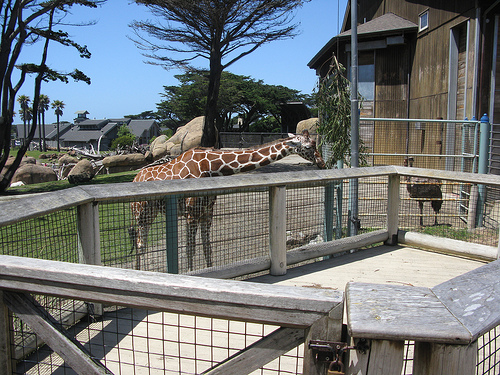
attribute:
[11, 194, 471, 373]
pen — empty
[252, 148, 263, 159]
spot — brown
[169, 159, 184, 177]
spot — brown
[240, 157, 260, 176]
spot — brown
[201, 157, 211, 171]
spot — brown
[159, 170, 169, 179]
spot — brown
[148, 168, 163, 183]
spot — brown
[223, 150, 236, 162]
spot — brown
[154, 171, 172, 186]
spot — brown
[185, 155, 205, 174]
spot — brown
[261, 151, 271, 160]
spot — brown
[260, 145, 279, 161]
spot — brown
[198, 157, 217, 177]
spot — brown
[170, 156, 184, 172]
spot — brown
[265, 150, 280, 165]
spot — brown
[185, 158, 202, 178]
spot — brown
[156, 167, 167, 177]
spot — brown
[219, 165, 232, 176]
spot — brown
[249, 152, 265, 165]
spot — brown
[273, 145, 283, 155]
spot — brown